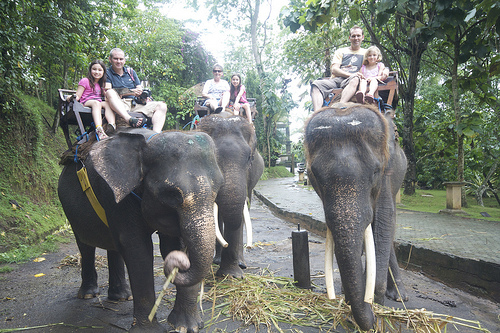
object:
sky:
[134, 0, 326, 145]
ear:
[87, 129, 145, 204]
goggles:
[210, 68, 223, 74]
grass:
[399, 188, 500, 223]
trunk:
[322, 194, 376, 331]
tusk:
[360, 221, 376, 303]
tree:
[183, 1, 298, 171]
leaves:
[212, 1, 228, 10]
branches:
[261, 20, 268, 58]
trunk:
[392, 56, 419, 198]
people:
[198, 62, 232, 114]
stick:
[147, 265, 180, 323]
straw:
[199, 261, 492, 331]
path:
[0, 190, 500, 331]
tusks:
[213, 200, 255, 247]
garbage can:
[443, 181, 466, 210]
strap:
[75, 168, 108, 226]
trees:
[0, 0, 220, 131]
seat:
[54, 88, 107, 149]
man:
[308, 24, 390, 111]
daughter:
[352, 39, 379, 105]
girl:
[228, 73, 253, 125]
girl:
[75, 58, 116, 140]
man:
[100, 47, 170, 133]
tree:
[278, 0, 500, 195]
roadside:
[252, 166, 500, 263]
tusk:
[322, 225, 338, 302]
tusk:
[242, 199, 255, 250]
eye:
[369, 163, 380, 177]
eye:
[164, 184, 182, 198]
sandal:
[128, 116, 148, 128]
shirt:
[331, 45, 366, 79]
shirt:
[203, 78, 230, 104]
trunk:
[213, 182, 247, 231]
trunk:
[162, 201, 219, 285]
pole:
[290, 230, 313, 287]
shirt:
[355, 62, 387, 83]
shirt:
[77, 76, 102, 106]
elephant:
[303, 101, 410, 331]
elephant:
[193, 111, 264, 282]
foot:
[165, 309, 205, 333]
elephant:
[59, 118, 222, 332]